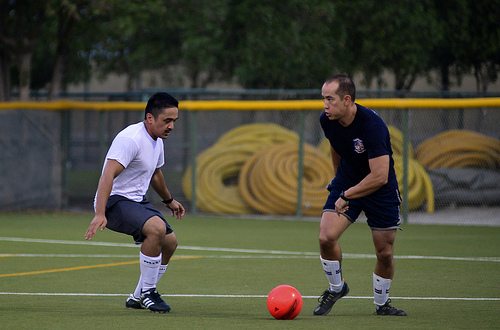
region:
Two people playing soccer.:
[85, 72, 411, 323]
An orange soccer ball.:
[263, 282, 303, 324]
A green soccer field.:
[2, 213, 497, 328]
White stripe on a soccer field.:
[2, 285, 495, 307]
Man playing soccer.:
[315, 70, 410, 319]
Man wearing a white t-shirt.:
[84, 88, 192, 317]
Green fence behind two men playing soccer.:
[5, 83, 496, 228]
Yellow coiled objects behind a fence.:
[185, 108, 496, 223]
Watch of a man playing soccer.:
[336, 190, 356, 208]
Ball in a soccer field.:
[263, 280, 304, 321]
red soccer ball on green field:
[262, 280, 304, 321]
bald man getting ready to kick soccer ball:
[308, 73, 415, 321]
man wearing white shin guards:
[312, 254, 397, 305]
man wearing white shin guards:
[133, 250, 169, 296]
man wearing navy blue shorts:
[101, 196, 173, 239]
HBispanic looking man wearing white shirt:
[95, 120, 165, 205]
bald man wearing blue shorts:
[320, 187, 405, 230]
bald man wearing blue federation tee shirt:
[319, 105, 396, 180]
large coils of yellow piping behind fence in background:
[177, 120, 499, 216]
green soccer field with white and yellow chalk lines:
[6, 218, 498, 325]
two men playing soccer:
[86, 73, 406, 312]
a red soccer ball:
[265, 287, 297, 321]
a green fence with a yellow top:
[1, 103, 498, 215]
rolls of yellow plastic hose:
[182, 121, 497, 208]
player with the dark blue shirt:
[314, 78, 407, 313]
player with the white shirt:
[87, 93, 185, 313]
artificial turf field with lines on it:
[2, 215, 497, 328]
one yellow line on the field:
[2, 256, 192, 276]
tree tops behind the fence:
[2, 1, 496, 95]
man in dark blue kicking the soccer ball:
[264, 76, 405, 315]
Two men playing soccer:
[73, 70, 416, 323]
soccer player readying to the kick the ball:
[267, 73, 409, 318]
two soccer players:
[80, 78, 412, 315]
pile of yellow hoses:
[182, 118, 497, 231]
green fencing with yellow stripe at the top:
[5, 94, 499, 232]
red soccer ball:
[265, 278, 301, 316]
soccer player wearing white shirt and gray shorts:
[91, 80, 199, 315]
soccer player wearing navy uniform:
[307, 72, 410, 317]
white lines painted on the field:
[5, 222, 499, 309]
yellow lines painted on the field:
[2, 251, 191, 293]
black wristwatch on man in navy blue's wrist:
[340, 189, 352, 203]